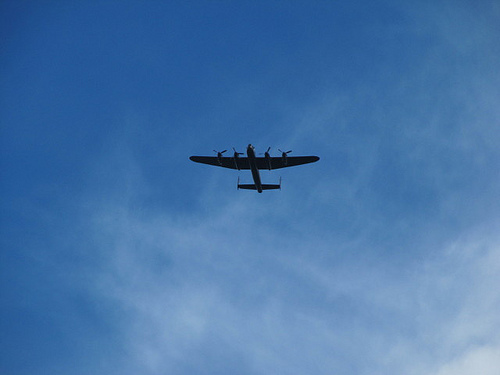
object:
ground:
[330, 195, 345, 237]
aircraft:
[185, 140, 325, 198]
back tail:
[234, 176, 285, 193]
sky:
[0, 1, 498, 373]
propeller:
[260, 143, 273, 162]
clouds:
[42, 122, 188, 369]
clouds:
[117, 206, 471, 352]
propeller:
[277, 145, 294, 157]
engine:
[226, 149, 243, 172]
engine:
[217, 150, 226, 160]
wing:
[256, 149, 317, 170]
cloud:
[157, 274, 194, 309]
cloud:
[273, 277, 330, 311]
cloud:
[306, 192, 362, 228]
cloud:
[239, 213, 292, 256]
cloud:
[167, 166, 227, 210]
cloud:
[269, 196, 324, 219]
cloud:
[236, 204, 278, 230]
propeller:
[230, 145, 244, 163]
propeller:
[211, 147, 228, 161]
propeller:
[228, 144, 245, 159]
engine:
[260, 148, 294, 158]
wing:
[191, 151, 252, 170]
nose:
[246, 142, 256, 160]